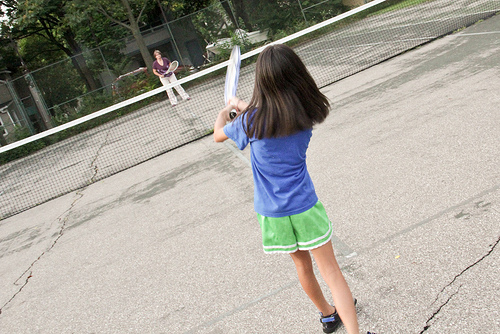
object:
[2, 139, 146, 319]
cement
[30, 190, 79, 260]
crack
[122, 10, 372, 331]
tennis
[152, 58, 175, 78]
shirt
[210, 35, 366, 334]
female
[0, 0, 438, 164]
net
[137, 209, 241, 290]
concrete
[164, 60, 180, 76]
racket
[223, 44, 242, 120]
racket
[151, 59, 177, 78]
coat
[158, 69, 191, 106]
pants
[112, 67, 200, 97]
vehicle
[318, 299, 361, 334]
shoe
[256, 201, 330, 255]
shorts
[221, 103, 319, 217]
shirt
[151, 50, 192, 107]
lady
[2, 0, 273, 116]
fence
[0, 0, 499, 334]
court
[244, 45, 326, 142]
hair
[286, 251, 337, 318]
leg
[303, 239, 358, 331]
leg